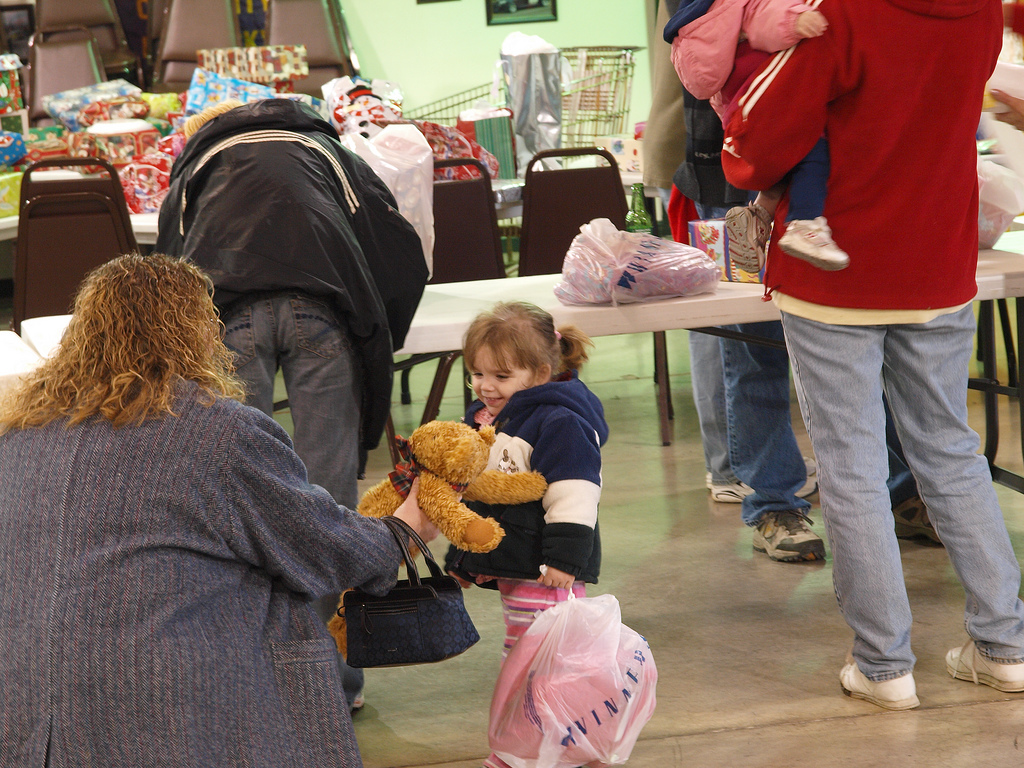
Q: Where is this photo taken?
A: In a large room.